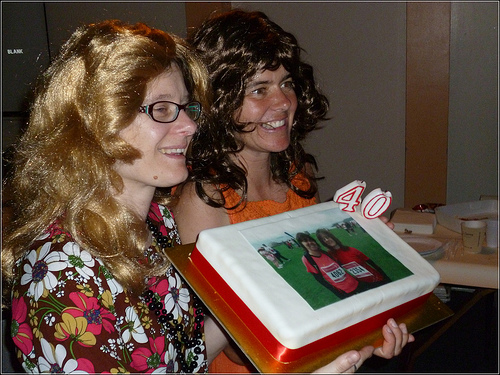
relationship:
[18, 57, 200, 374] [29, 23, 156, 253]
woman wearing wig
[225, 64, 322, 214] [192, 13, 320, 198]
woman wearing wig